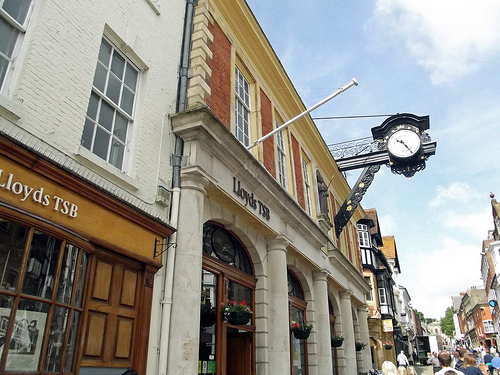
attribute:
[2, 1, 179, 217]
wall — painted, brick, white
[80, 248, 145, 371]
door — paneled, wood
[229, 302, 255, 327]
basket — hanging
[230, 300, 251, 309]
flowers — red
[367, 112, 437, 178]
clock — black, ornate, mounted, antique, old fashioned, hanging, white, fixed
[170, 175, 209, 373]
pillar — stone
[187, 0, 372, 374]
building — brick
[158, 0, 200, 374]
downspout — metal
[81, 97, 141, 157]
panes — glass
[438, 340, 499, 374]
people — walking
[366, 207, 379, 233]
roof — steep, sloped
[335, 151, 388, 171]
beam — decorative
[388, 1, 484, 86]
clouds — puffy, white, fluffy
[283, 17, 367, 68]
sky — blue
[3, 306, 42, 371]
advertisement — vintage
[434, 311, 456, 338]
trees — green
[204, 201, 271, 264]
archway — stone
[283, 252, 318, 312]
archway — stone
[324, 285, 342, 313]
archway — stone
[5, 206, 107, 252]
frame — wood, brown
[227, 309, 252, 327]
plant hanger — iron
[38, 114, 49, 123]
brick — white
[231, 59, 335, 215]
window — attached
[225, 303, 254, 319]
flower pot — hanging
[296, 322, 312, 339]
flower pot — hanging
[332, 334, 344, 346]
flower pot — hanging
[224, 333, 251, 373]
door — open